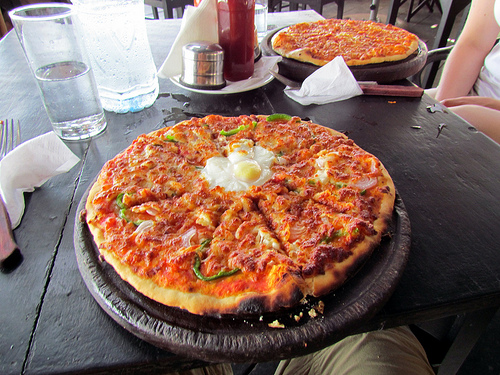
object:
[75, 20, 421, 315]
wood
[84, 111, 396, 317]
pizza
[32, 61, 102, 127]
water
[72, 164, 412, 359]
plate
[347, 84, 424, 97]
handle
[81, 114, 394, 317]
crust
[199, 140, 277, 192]
egg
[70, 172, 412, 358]
tray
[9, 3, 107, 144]
glass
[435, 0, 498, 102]
arm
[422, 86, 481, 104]
leg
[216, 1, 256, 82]
ketchup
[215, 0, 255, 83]
bottle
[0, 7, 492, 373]
table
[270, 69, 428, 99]
silverware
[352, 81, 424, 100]
handle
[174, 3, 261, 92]
condiments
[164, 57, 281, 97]
plate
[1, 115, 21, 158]
fork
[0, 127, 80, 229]
napkin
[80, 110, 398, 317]
pizza pie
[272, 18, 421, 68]
pizza pie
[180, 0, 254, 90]
bottles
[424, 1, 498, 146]
person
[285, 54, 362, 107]
napkin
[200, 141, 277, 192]
middle